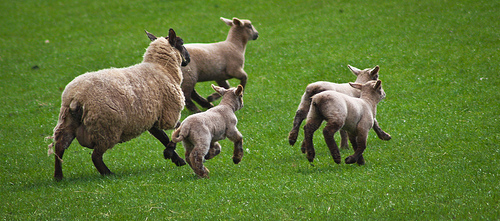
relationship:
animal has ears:
[167, 83, 245, 180] [344, 62, 378, 75]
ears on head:
[344, 62, 378, 75] [346, 62, 382, 83]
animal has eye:
[167, 83, 245, 180] [240, 22, 252, 30]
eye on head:
[240, 22, 252, 30] [217, 10, 258, 43]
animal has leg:
[167, 83, 245, 180] [323, 113, 348, 167]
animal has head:
[167, 83, 245, 180] [217, 15, 257, 46]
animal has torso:
[167, 83, 245, 180] [194, 108, 230, 140]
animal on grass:
[167, 83, 245, 180] [4, 0, 496, 218]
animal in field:
[301, 79, 386, 165] [9, 6, 483, 212]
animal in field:
[167, 83, 245, 180] [9, 6, 483, 212]